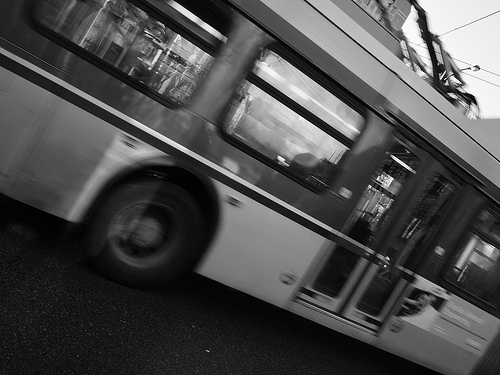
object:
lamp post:
[455, 61, 481, 76]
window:
[432, 191, 499, 315]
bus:
[91, 169, 215, 297]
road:
[8, 217, 332, 373]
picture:
[14, 19, 487, 369]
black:
[169, 188, 191, 210]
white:
[246, 230, 283, 257]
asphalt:
[19, 234, 306, 374]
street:
[2, 202, 439, 373]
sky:
[440, 2, 498, 48]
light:
[224, 195, 244, 212]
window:
[149, 28, 211, 102]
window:
[219, 39, 370, 196]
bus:
[1, 1, 498, 373]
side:
[211, 40, 362, 278]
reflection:
[66, 85, 267, 220]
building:
[351, 0, 413, 35]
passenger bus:
[4, 3, 499, 373]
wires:
[391, 1, 498, 95]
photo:
[4, 0, 498, 368]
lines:
[431, 5, 494, 66]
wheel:
[88, 163, 220, 283]